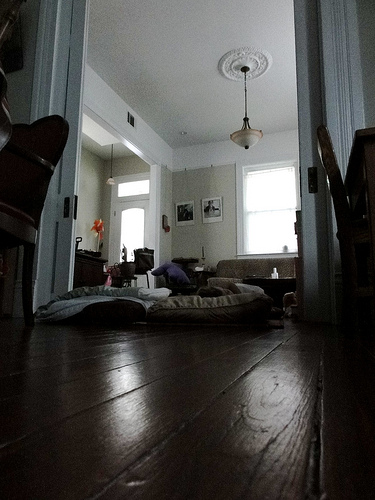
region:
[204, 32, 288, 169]
light fixture on a roof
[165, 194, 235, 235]
two pictures on a wall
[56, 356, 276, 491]
natural wood floor with gloss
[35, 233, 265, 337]
pillows and a dog bed on floor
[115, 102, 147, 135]
air vent on side of pillar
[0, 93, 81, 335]
part of wood chair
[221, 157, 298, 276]
window letting in window light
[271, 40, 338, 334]
sliding door in in its holder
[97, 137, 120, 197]
small hanging light ficture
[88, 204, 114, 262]
orange decoration on a stand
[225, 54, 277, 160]
A lamp hanging from the ceiling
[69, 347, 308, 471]
The floor is hardwood.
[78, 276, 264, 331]
Pillows on the floor.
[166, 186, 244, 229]
Pictures hanging on the wall.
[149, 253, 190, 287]
Pillow on the chair.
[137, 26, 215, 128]
The ceiling is white.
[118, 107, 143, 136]
Vent attached to the wall.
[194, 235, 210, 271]
A candle on the table.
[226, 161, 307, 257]
A window by the sofa.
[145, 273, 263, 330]
Cushions on the floor.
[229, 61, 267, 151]
light fixture hanging from ceiling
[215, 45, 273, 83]
medallion around light fixture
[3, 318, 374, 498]
dark brown wooden floor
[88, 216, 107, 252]
floral arrangement on chest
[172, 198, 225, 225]
art work affixed to wall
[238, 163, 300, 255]
window covered with blinds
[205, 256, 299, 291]
sofa beneath window in living room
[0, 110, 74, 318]
chair at dining table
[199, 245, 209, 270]
candle holder with purple candle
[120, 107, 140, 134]
air vent above wooden door frame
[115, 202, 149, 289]
a front door with a window in it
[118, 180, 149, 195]
the window over the door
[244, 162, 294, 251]
a window in the living room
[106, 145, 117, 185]
a small pendant light by the door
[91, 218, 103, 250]
an orange flower by the door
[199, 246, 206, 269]
a candle stick to the left of the window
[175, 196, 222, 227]
two photos on the wall left of window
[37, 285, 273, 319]
large pillows on the floor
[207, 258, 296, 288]
a couch under the window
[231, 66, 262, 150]
a light fixture handing from ceiling in living room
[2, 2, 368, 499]
a living room with white walls and ceiling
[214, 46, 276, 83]
fancy plaster ceiling rose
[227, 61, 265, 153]
a ceiling light on a long chain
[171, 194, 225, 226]
two black and white prints on a wall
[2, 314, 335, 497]
polished wooden floor boards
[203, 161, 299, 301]
sofa in front of a window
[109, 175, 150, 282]
rectangular window over a glass door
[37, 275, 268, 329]
dog beds on the floor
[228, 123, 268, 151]
glass shade on a ceiling light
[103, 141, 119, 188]
ceiling light on a chain